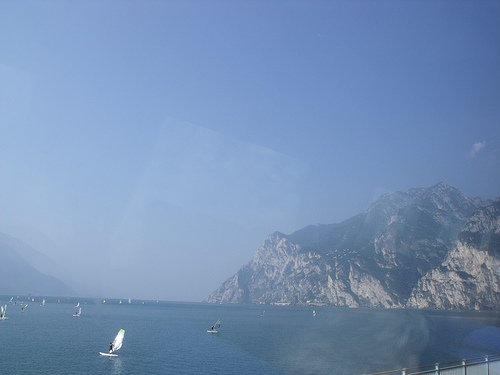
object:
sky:
[2, 3, 498, 301]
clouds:
[468, 134, 489, 157]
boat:
[99, 327, 125, 357]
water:
[268, 331, 416, 363]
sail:
[108, 325, 125, 356]